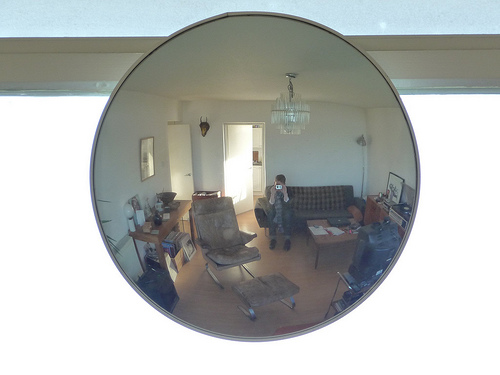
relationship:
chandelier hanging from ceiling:
[268, 92, 311, 143] [242, 24, 314, 70]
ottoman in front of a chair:
[233, 272, 305, 311] [190, 193, 266, 289]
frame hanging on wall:
[139, 136, 155, 183] [100, 144, 138, 186]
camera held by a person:
[275, 182, 287, 193] [267, 174, 299, 254]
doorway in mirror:
[219, 115, 272, 217] [80, 10, 429, 346]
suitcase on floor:
[133, 266, 192, 319] [185, 288, 231, 324]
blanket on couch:
[293, 181, 346, 216] [255, 182, 370, 232]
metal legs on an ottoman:
[239, 302, 260, 321] [233, 272, 305, 311]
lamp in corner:
[352, 125, 372, 216] [356, 105, 370, 134]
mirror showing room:
[80, 10, 429, 346] [111, 101, 403, 298]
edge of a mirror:
[220, 7, 290, 31] [80, 10, 429, 346]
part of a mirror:
[133, 51, 156, 65] [80, 10, 429, 346]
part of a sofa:
[312, 188, 321, 217] [255, 182, 370, 232]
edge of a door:
[183, 123, 192, 131] [166, 120, 201, 204]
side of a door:
[174, 136, 184, 168] [166, 120, 201, 204]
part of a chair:
[215, 229, 237, 237] [190, 193, 266, 289]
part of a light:
[362, 157, 367, 168] [360, 141, 365, 147]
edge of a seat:
[250, 250, 263, 261] [190, 193, 266, 289]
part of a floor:
[224, 299, 237, 327] [185, 288, 231, 324]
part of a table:
[145, 232, 164, 255] [130, 188, 195, 250]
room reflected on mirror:
[111, 101, 403, 298] [80, 10, 429, 346]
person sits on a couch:
[267, 174, 299, 254] [255, 182, 370, 232]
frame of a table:
[139, 136, 155, 183] [130, 188, 195, 250]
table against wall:
[130, 188, 195, 250] [100, 144, 138, 186]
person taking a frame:
[267, 174, 299, 254] [139, 136, 155, 183]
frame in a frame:
[139, 136, 155, 183] [139, 136, 158, 144]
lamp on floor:
[352, 125, 372, 216] [185, 288, 231, 324]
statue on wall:
[196, 116, 213, 138] [100, 144, 138, 186]